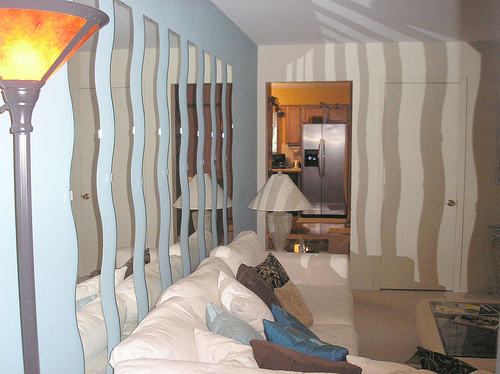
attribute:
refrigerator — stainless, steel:
[296, 126, 354, 220]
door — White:
[377, 73, 472, 293]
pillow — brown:
[248, 335, 363, 372]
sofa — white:
[131, 233, 353, 371]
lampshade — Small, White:
[248, 172, 313, 212]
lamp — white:
[246, 167, 317, 254]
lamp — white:
[248, 185, 329, 253]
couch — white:
[139, 294, 209, 351]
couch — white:
[159, 190, 435, 372]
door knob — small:
[443, 194, 455, 207]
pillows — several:
[216, 235, 363, 368]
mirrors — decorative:
[140, 12, 239, 282]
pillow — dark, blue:
[263, 319, 348, 361]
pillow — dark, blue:
[271, 300, 318, 336]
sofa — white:
[118, 204, 368, 371]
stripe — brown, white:
[268, 171, 285, 215]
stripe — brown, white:
[282, 179, 302, 214]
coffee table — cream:
[405, 291, 499, 372]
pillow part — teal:
[263, 316, 298, 343]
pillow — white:
[193, 323, 260, 368]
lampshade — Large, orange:
[2, 2, 123, 104]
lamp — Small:
[245, 170, 313, 254]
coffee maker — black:
[272, 152, 285, 168]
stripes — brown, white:
[362, 42, 456, 296]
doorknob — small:
[440, 193, 458, 213]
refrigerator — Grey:
[296, 120, 346, 218]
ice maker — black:
[305, 147, 318, 167]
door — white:
[356, 75, 464, 296]